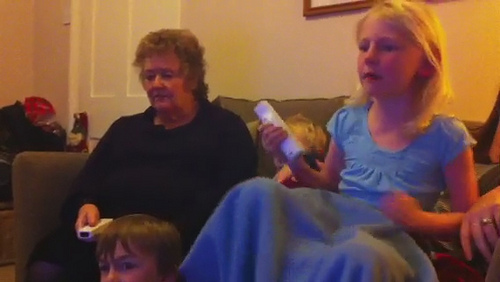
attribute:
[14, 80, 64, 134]
flower — red 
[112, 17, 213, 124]
grandma — sleeping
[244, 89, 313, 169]
wii controller — in young girl's hand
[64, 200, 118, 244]
wii controller — in old lady's hand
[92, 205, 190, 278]
boy — young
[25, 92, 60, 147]
bag — red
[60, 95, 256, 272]
shirt — black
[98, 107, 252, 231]
shirt — black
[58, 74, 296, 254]
shirt — black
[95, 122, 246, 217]
shirt — black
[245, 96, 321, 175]
wii controller — white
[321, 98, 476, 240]
shirt — blue 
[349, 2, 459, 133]
hair — light  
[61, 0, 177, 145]
door — white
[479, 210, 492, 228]
ring — gold 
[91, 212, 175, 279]
child's head — young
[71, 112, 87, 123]
door knob — brass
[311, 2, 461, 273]
girl — young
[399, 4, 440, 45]
hair — blond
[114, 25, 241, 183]
lady — older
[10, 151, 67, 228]
couch arm — tan